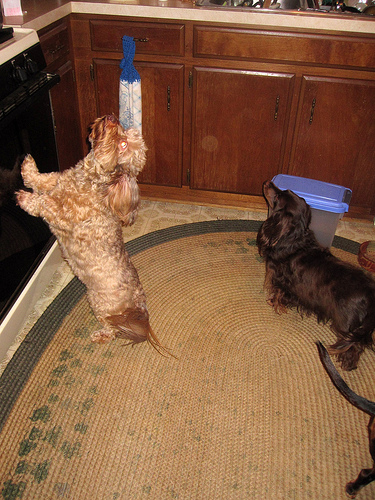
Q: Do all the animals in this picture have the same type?
A: Yes, all the animals are dogs.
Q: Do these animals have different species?
A: No, all the animals are dogs.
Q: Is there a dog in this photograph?
A: Yes, there is a dog.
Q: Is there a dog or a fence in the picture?
A: Yes, there is a dog.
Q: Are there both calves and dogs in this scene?
A: No, there is a dog but no calves.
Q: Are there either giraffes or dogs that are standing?
A: Yes, the dog is standing.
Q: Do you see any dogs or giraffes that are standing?
A: Yes, the dog is standing.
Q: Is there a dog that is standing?
A: Yes, there is a dog that is standing.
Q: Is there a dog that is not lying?
A: Yes, there is a dog that is standing.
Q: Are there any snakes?
A: No, there are no snakes.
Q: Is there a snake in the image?
A: No, there are no snakes.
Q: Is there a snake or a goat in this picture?
A: No, there are no snakes or goats.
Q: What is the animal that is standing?
A: The animal is a dog.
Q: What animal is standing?
A: The animal is a dog.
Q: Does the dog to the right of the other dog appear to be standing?
A: Yes, the dog is standing.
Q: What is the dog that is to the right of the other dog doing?
A: The dog is standing.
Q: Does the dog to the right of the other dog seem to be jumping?
A: No, the dog is standing.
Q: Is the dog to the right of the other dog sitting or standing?
A: The dog is standing.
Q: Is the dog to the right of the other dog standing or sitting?
A: The dog is standing.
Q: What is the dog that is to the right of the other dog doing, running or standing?
A: The dog is standing.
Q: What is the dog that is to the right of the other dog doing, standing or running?
A: The dog is standing.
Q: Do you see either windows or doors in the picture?
A: Yes, there is a door.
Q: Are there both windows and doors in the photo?
A: No, there is a door but no windows.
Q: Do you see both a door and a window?
A: No, there is a door but no windows.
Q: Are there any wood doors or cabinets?
A: Yes, there is a wood door.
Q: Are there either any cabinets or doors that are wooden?
A: Yes, the door is wooden.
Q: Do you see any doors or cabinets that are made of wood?
A: Yes, the door is made of wood.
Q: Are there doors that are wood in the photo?
A: Yes, there is a wood door.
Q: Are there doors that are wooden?
A: Yes, there is a door that is wooden.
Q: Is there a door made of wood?
A: Yes, there is a door that is made of wood.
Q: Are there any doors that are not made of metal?
A: Yes, there is a door that is made of wood.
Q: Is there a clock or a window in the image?
A: No, there are no windows or clocks.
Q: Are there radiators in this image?
A: No, there are no radiators.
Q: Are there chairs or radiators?
A: No, there are no radiators or chairs.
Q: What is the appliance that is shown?
A: The appliance is a stove.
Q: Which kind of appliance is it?
A: The appliance is a stove.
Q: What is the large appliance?
A: The appliance is a stove.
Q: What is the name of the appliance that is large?
A: The appliance is a stove.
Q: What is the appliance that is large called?
A: The appliance is a stove.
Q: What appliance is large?
A: The appliance is a stove.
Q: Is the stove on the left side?
A: Yes, the stove is on the left of the image.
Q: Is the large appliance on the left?
A: Yes, the stove is on the left of the image.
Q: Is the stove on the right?
A: No, the stove is on the left of the image.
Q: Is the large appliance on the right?
A: No, the stove is on the left of the image.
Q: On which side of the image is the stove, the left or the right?
A: The stove is on the left of the image.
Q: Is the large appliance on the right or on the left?
A: The stove is on the left of the image.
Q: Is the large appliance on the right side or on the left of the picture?
A: The stove is on the left of the image.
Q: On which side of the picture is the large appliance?
A: The stove is on the left of the image.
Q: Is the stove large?
A: Yes, the stove is large.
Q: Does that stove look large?
A: Yes, the stove is large.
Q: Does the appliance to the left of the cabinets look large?
A: Yes, the stove is large.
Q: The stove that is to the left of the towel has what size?
A: The stove is large.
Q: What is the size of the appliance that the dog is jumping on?
A: The stove is large.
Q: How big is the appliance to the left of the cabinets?
A: The stove is large.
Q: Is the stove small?
A: No, the stove is large.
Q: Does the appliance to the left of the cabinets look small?
A: No, the stove is large.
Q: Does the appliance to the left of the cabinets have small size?
A: No, the stove is large.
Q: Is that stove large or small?
A: The stove is large.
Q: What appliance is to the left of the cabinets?
A: The appliance is a stove.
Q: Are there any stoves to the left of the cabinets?
A: Yes, there is a stove to the left of the cabinets.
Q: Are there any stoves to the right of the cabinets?
A: No, the stove is to the left of the cabinets.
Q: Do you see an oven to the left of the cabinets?
A: No, there is a stove to the left of the cabinets.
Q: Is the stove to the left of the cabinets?
A: Yes, the stove is to the left of the cabinets.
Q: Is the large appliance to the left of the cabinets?
A: Yes, the stove is to the left of the cabinets.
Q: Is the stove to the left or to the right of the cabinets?
A: The stove is to the left of the cabinets.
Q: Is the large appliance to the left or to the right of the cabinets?
A: The stove is to the left of the cabinets.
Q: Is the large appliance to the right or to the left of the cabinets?
A: The stove is to the left of the cabinets.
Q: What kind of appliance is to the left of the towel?
A: The appliance is a stove.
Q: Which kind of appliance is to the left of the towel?
A: The appliance is a stove.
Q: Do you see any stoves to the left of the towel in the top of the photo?
A: Yes, there is a stove to the left of the towel.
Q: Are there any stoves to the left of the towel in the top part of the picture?
A: Yes, there is a stove to the left of the towel.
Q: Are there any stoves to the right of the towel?
A: No, the stove is to the left of the towel.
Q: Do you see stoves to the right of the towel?
A: No, the stove is to the left of the towel.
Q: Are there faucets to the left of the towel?
A: No, there is a stove to the left of the towel.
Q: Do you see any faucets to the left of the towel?
A: No, there is a stove to the left of the towel.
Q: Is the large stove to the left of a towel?
A: Yes, the stove is to the left of a towel.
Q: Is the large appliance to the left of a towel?
A: Yes, the stove is to the left of a towel.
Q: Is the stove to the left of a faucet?
A: No, the stove is to the left of a towel.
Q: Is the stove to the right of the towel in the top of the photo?
A: No, the stove is to the left of the towel.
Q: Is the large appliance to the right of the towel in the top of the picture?
A: No, the stove is to the left of the towel.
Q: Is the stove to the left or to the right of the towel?
A: The stove is to the left of the towel.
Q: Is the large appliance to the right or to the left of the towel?
A: The stove is to the left of the towel.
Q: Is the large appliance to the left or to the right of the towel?
A: The stove is to the left of the towel.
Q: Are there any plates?
A: No, there are no plates.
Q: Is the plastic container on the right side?
A: Yes, the container is on the right of the image.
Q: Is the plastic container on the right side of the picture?
A: Yes, the container is on the right of the image.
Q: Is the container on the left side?
A: No, the container is on the right of the image.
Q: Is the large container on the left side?
A: No, the container is on the right of the image.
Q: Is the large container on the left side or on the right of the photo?
A: The container is on the right of the image.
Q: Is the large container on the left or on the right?
A: The container is on the right of the image.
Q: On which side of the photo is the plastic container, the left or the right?
A: The container is on the right of the image.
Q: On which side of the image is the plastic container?
A: The container is on the right of the image.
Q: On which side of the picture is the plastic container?
A: The container is on the right of the image.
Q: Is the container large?
A: Yes, the container is large.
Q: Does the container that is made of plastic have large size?
A: Yes, the container is large.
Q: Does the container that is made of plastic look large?
A: Yes, the container is large.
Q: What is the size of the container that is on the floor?
A: The container is large.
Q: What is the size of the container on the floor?
A: The container is large.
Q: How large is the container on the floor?
A: The container is large.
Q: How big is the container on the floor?
A: The container is large.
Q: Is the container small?
A: No, the container is large.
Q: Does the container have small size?
A: No, the container is large.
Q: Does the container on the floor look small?
A: No, the container is large.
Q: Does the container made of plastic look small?
A: No, the container is large.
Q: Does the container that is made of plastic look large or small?
A: The container is large.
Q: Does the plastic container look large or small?
A: The container is large.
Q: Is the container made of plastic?
A: Yes, the container is made of plastic.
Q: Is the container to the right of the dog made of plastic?
A: Yes, the container is made of plastic.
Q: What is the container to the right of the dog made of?
A: The container is made of plastic.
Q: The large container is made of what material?
A: The container is made of plastic.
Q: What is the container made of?
A: The container is made of plastic.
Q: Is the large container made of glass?
A: No, the container is made of plastic.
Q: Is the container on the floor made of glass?
A: No, the container is made of plastic.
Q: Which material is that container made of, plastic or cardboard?
A: The container is made of plastic.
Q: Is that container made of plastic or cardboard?
A: The container is made of plastic.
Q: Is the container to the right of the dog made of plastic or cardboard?
A: The container is made of plastic.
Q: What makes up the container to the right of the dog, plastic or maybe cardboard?
A: The container is made of plastic.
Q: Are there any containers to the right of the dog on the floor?
A: Yes, there is a container to the right of the dog.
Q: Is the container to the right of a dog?
A: Yes, the container is to the right of a dog.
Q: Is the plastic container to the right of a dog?
A: Yes, the container is to the right of a dog.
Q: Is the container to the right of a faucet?
A: No, the container is to the right of a dog.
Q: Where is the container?
A: The container is on the floor.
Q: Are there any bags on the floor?
A: No, there is a container on the floor.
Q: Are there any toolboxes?
A: No, there are no toolboxes.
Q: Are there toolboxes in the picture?
A: No, there are no toolboxes.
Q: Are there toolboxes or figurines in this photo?
A: No, there are no toolboxes or figurines.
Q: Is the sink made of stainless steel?
A: Yes, the sink is made of stainless steel.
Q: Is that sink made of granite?
A: No, the sink is made of stainless steel.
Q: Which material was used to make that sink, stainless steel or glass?
A: The sink is made of stainless steel.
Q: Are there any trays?
A: No, there are no trays.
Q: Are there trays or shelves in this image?
A: No, there are no trays or shelves.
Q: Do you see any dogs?
A: Yes, there is a dog.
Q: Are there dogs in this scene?
A: Yes, there is a dog.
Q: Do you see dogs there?
A: Yes, there is a dog.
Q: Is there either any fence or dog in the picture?
A: Yes, there is a dog.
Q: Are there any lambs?
A: No, there are no lambs.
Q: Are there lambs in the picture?
A: No, there are no lambs.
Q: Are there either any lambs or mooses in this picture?
A: No, there are no lambs or mooses.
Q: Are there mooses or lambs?
A: No, there are no lambs or mooses.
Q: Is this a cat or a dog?
A: This is a dog.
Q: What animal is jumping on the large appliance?
A: The dog is jumping on the stove.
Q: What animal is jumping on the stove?
A: The dog is jumping on the stove.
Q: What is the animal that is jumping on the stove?
A: The animal is a dog.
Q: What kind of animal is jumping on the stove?
A: The animal is a dog.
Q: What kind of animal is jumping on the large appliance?
A: The animal is a dog.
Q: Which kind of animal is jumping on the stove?
A: The animal is a dog.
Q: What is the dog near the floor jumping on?
A: The dog is jumping on the stove.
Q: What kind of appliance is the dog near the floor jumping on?
A: The dog is jumping on the stove.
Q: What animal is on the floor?
A: The animal is a dog.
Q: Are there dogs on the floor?
A: Yes, there is a dog on the floor.